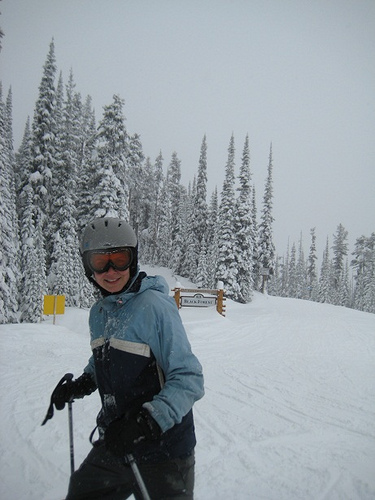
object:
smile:
[98, 274, 129, 291]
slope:
[278, 297, 341, 323]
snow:
[221, 201, 236, 255]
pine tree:
[257, 144, 278, 294]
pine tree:
[236, 132, 255, 301]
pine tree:
[304, 225, 317, 298]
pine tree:
[179, 135, 207, 274]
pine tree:
[0, 92, 25, 320]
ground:
[0, 305, 375, 500]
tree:
[283, 236, 291, 297]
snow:
[0, 290, 374, 498]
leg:
[62, 443, 131, 499]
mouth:
[104, 275, 122, 286]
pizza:
[250, 309, 333, 384]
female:
[41, 216, 206, 498]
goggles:
[83, 249, 133, 271]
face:
[86, 250, 129, 295]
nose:
[107, 268, 118, 279]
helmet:
[80, 215, 138, 287]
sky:
[2, 0, 370, 182]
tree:
[351, 229, 375, 313]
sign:
[171, 287, 225, 314]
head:
[78, 214, 144, 292]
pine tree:
[257, 137, 282, 298]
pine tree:
[185, 130, 211, 282]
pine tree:
[77, 88, 133, 224]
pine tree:
[24, 36, 65, 244]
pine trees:
[289, 240, 299, 297]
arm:
[77, 352, 98, 396]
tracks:
[234, 363, 331, 429]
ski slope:
[152, 265, 347, 462]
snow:
[194, 142, 207, 231]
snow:
[329, 222, 352, 304]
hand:
[52, 372, 85, 412]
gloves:
[106, 408, 157, 458]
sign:
[40, 293, 66, 315]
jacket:
[82, 267, 206, 436]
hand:
[104, 410, 158, 457]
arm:
[143, 302, 205, 411]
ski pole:
[67, 375, 75, 496]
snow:
[248, 224, 258, 253]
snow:
[229, 278, 244, 295]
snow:
[153, 227, 169, 243]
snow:
[307, 252, 316, 264]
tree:
[328, 224, 347, 305]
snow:
[28, 169, 48, 186]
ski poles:
[123, 451, 152, 497]